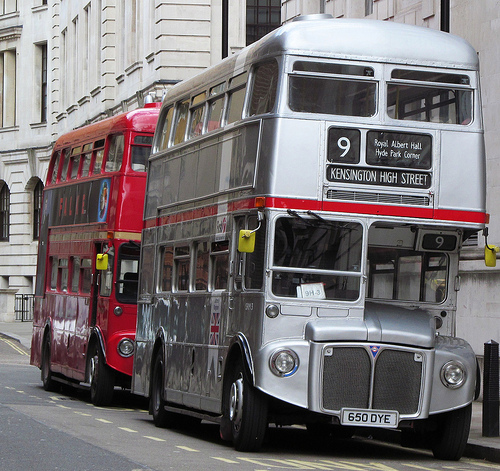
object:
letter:
[382, 413, 394, 427]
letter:
[419, 170, 430, 188]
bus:
[29, 101, 166, 403]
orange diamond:
[94, 176, 112, 223]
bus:
[130, 18, 487, 452]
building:
[3, 0, 222, 337]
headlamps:
[271, 349, 301, 378]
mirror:
[92, 252, 109, 273]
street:
[0, 327, 237, 471]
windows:
[26, 40, 52, 128]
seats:
[292, 79, 373, 115]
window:
[382, 66, 471, 123]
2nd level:
[280, 19, 479, 70]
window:
[101, 133, 127, 177]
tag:
[341, 406, 400, 427]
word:
[373, 138, 423, 160]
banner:
[328, 127, 361, 163]